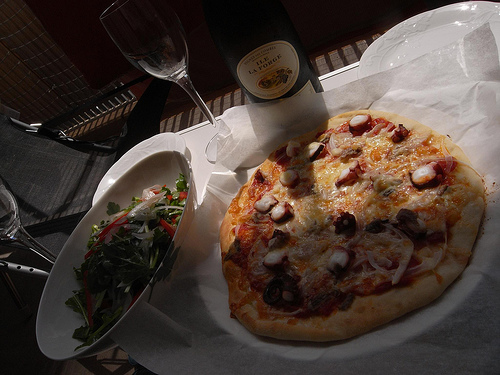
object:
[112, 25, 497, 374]
paper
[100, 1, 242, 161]
glass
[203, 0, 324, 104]
wine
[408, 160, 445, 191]
onion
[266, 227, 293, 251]
onion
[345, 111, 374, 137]
onion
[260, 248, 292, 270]
onion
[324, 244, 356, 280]
onion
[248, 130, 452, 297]
cheese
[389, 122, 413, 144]
purple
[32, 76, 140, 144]
metal grating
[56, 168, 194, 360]
salad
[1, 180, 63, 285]
glass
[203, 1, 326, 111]
bottle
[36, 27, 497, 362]
table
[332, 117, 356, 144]
ground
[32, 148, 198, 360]
plate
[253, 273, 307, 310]
olive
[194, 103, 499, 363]
plate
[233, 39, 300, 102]
label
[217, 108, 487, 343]
pizza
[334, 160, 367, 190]
radish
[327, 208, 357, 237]
radish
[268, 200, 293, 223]
radish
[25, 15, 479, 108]
floor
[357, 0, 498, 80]
plate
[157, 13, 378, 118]
shadow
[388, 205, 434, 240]
topping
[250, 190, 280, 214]
meat